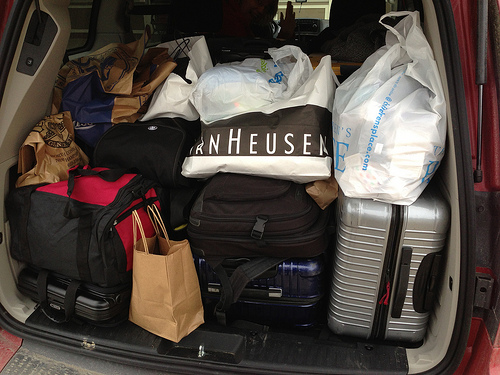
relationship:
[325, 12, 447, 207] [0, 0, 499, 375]
bag in car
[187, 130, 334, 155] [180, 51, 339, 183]
brand info on bag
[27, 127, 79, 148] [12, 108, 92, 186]
logo on bag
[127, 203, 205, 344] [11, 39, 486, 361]
bag in vehicle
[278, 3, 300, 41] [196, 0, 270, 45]
hand near driver's seat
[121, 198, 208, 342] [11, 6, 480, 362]
bag stuffed in car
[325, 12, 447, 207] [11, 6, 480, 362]
bag stuffed in car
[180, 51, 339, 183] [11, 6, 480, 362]
bag stuffed in car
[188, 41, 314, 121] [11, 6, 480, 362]
bag stuffed in car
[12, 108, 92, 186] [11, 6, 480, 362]
bag stuffed in car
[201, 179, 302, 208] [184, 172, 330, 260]
small pocket sewn on bag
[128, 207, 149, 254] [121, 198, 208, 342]
handle attached to bag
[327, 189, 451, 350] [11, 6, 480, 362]
suitcase in car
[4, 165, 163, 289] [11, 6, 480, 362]
duffel bag in car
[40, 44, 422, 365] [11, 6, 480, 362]
bags in car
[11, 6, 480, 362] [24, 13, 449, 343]
car full of bags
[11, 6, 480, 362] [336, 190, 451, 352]
car filled with suitcase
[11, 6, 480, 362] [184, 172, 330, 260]
car filled with bag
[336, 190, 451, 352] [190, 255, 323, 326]
suitcase filled with suitcase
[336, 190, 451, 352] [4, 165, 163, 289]
suitcase filled with duffel bag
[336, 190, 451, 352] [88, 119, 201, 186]
suitcase filled with suitcases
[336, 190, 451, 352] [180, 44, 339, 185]
suitcase filled with bag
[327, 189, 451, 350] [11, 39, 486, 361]
suitcase in vehicle